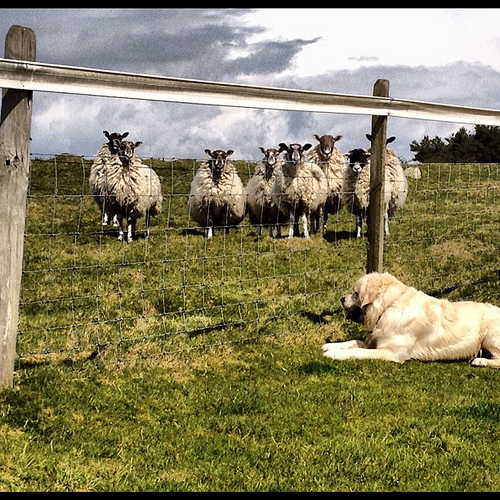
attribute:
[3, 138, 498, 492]
green pasture — large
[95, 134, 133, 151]
head — black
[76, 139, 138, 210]
sheep — white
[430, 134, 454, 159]
trees — distant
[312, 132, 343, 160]
head — black, white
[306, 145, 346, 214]
sheep body — fluffy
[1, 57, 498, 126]
railing — white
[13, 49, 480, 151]
rail — white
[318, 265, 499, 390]
dog laying — cream colored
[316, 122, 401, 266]
post — wooden, brown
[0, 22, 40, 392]
post — wooden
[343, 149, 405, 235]
sheep — white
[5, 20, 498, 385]
fence — wire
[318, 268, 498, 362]
dog — good, obedient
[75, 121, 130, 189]
sheep — white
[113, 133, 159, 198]
sheep — white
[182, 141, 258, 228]
sheep — white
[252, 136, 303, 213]
sheep — white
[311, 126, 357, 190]
sheep — white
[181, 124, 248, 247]
sheep — white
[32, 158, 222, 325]
fence — chicken wire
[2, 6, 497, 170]
sky — gray, cloudy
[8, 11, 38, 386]
pole — wood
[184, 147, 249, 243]
sheep — tall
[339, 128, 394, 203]
head — black, fluffy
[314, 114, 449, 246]
sheep — white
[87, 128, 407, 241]
sheep — white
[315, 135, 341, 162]
head — brown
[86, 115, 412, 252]
flock — small